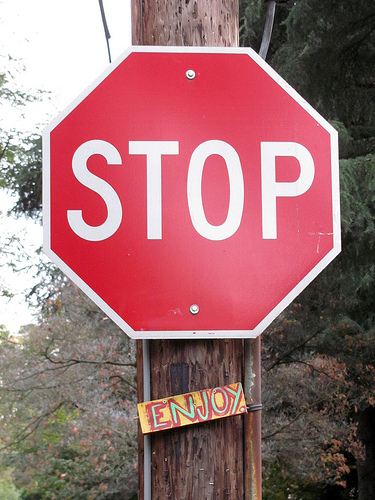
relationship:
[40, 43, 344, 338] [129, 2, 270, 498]
sign on pole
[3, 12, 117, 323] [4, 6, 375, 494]
sky beside trees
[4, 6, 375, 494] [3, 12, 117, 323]
trees beside sky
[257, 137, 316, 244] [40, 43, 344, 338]
letter p on sign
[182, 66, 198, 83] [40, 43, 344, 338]
top screw on sign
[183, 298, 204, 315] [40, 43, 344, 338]
bottom screw on sign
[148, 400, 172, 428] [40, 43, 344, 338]
letter e on sign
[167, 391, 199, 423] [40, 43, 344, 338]
letter n on sign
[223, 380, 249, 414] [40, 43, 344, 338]
letter y on sign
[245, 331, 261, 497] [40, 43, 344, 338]
pipe under sign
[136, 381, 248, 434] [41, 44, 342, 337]
enjoy sign under sign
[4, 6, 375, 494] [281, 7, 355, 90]
trees with leaves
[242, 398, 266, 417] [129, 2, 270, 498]
clips are in pole